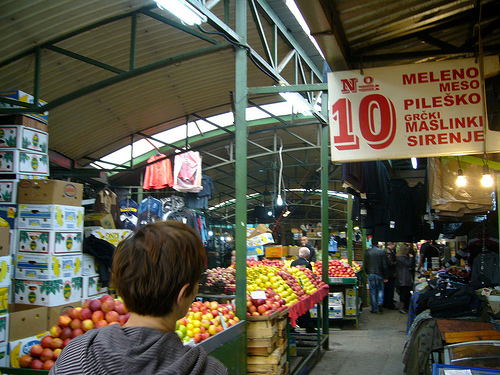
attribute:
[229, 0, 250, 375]
pole — metal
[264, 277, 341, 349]
table — covered 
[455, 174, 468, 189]
bulb — lit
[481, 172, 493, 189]
bulb — lit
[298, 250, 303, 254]
hair — gray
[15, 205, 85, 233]
box — white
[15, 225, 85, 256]
box — white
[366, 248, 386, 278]
jacket — black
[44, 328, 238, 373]
jacket — red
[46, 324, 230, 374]
hoodie — striped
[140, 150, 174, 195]
coat — red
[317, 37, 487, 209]
sign — red, white 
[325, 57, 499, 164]
sign — white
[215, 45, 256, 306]
board — wood, tall, green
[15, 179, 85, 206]
box — brown, cardboard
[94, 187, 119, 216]
coat — brown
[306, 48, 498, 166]
sign — white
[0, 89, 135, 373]
boxes — stack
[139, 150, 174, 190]
jacket — red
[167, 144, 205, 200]
shirt — hanging 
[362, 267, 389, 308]
jeans — blue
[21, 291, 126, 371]
apples — red, Pile 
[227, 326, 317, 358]
boxes — white , green, yellow , blue , stacked 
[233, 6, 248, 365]
pole — tall, green, metal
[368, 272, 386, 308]
jeans — blue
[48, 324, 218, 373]
sweater — gray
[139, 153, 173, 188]
jacket — hanging 